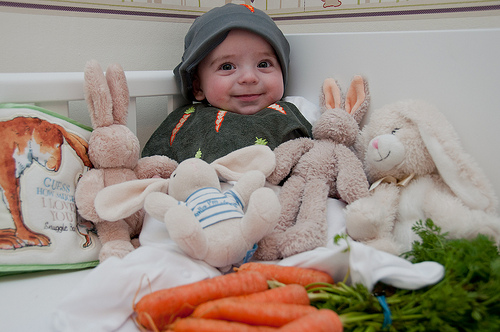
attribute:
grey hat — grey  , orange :
[173, 1, 288, 106]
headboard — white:
[1, 68, 183, 135]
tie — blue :
[366, 286, 394, 331]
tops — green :
[312, 227, 498, 329]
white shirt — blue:
[178, 187, 246, 227]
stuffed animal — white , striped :
[147, 149, 289, 261]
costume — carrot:
[172, 106, 307, 153]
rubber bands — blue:
[375, 292, 394, 330]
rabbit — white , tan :
[360, 103, 489, 258]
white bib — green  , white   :
[149, 97, 306, 179]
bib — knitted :
[0, 102, 107, 274]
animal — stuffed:
[255, 76, 370, 261]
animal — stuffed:
[95, 145, 282, 266]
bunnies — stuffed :
[75, 60, 498, 272]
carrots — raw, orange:
[230, 261, 335, 289]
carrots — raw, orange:
[133, 265, 266, 326]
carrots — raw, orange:
[194, 280, 319, 313]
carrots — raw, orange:
[201, 298, 318, 324]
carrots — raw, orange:
[273, 310, 341, 330]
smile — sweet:
[372, 150, 391, 164]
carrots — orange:
[122, 233, 309, 322]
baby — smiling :
[141, 1, 313, 161]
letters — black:
[38, 218, 74, 236]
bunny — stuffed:
[95, 141, 279, 266]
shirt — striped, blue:
[172, 186, 249, 228]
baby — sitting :
[135, 1, 335, 160]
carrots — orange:
[115, 215, 499, 329]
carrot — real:
[236, 262, 331, 286]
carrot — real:
[136, 269, 267, 326]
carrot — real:
[195, 294, 317, 318]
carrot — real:
[284, 310, 341, 330]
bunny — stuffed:
[356, 104, 497, 246]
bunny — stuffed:
[268, 72, 370, 259]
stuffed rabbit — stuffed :
[280, 97, 366, 234]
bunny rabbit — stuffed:
[71, 59, 178, 264]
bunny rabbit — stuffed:
[91, 143, 280, 271]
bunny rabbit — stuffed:
[255, 73, 373, 262]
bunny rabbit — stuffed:
[343, 97, 498, 252]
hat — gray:
[169, 2, 286, 98]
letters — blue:
[31, 173, 77, 204]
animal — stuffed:
[75, 57, 183, 266]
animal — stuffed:
[344, 98, 484, 270]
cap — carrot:
[173, 4, 291, 94]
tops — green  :
[332, 244, 472, 330]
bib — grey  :
[201, 108, 261, 151]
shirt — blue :
[175, 183, 246, 223]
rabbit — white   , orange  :
[276, 85, 350, 208]